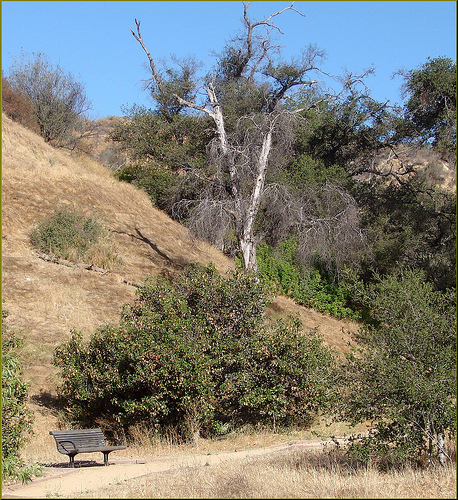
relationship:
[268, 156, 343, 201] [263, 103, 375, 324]
leaves on tree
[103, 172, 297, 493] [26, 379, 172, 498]
bush behind bench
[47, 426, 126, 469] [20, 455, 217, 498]
bench aside path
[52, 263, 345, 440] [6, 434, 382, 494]
shrubbery on path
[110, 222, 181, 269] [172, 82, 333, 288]
shadow on tree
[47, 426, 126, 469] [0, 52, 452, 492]
bench in park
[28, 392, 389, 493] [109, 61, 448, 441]
walking trail in forest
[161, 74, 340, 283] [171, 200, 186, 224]
tree has no leaves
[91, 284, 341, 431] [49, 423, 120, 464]
tree next to bench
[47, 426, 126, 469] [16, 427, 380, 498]
bench along a walking path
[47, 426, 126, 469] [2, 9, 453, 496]
bench in park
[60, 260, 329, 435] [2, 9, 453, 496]
trees in park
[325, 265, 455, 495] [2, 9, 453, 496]
trees in park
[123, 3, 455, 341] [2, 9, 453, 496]
trees in park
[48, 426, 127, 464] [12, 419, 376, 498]
wooden bench on walkway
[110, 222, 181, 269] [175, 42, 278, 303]
shadow of tree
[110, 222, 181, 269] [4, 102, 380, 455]
shadow on hillside